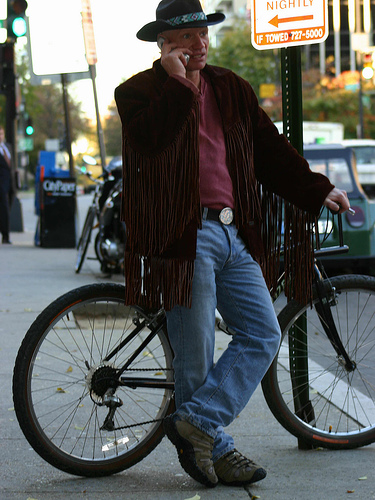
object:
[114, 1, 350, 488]
man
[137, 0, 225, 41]
hat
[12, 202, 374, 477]
bicycle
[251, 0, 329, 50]
sign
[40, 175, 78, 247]
newspaper box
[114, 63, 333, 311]
coat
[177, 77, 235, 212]
shirt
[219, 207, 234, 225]
belt buckle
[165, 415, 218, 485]
shoe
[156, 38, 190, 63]
phone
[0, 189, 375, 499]
sidewalk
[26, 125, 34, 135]
light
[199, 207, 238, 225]
belt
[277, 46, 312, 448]
pole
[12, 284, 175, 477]
tire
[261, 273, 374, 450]
front tire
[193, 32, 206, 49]
nose